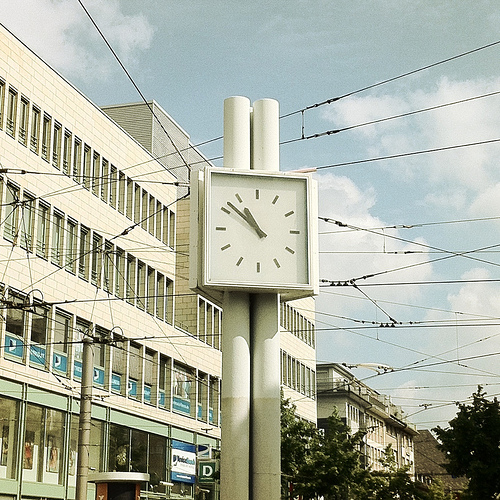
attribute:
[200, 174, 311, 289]
clock — part of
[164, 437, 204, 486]
sign — blue, white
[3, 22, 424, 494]
building — off white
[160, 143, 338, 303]
clock — white 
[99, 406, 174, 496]
window — part of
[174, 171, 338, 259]
face — White 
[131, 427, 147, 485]
window — part of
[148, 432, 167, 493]
window — part of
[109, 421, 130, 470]
window — part of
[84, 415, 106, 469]
window — part of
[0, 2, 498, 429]
power lines — black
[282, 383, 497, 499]
trees — few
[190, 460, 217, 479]
d — white, letter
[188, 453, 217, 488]
sign — green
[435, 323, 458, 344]
cloud — part of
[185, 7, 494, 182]
sky — blue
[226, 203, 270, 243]
hands — black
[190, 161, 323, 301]
clock — white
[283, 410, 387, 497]
trees — Green 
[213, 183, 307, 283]
numbers — black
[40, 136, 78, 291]
blinds — grey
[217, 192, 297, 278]
number — black, markings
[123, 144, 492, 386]
lines — power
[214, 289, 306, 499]
pole — white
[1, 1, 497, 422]
sky — cloudy